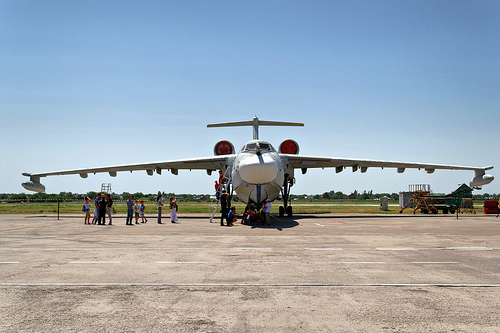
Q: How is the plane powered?
A: Jet engines.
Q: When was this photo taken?
A: During the day.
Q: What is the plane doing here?
A: It's on display.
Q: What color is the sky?
A: Blue.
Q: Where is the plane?
A: On the tarmac.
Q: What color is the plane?
A: Silver.